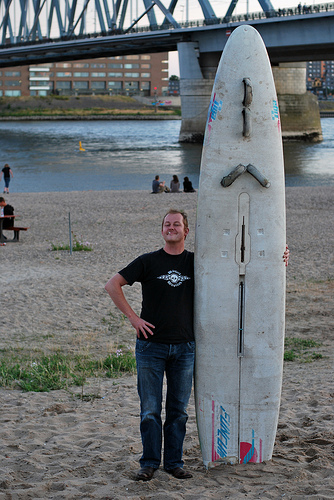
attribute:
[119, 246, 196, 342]
shirt — black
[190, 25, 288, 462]
surfboard — very tall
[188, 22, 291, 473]
board — white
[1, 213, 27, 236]
table — picnic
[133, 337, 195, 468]
jeans — blue